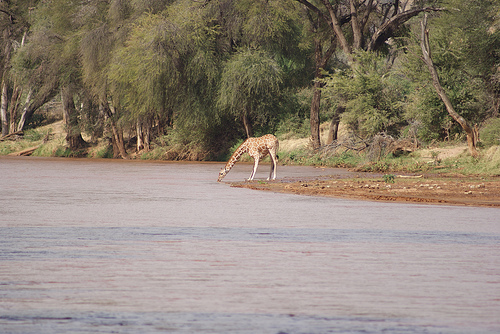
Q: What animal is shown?
A: A giraffe.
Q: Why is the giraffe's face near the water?
A: To drink.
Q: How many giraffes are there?
A: One.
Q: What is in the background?
A: Trees.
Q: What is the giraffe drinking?
A: Water.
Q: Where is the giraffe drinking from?
A: A river.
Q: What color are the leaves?
A: Green.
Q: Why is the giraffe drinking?
A: It is thirsty.